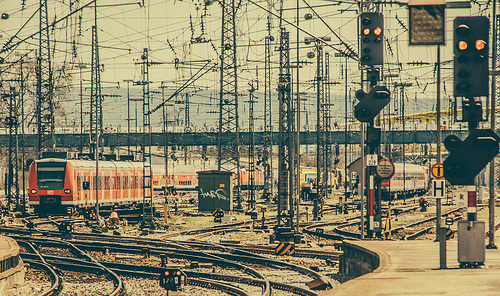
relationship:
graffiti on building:
[199, 186, 229, 202] [197, 171, 230, 213]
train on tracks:
[31, 146, 350, 207] [4, 194, 497, 296]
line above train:
[93, 10, 226, 25] [31, 146, 350, 207]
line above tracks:
[93, 10, 226, 25] [4, 194, 497, 296]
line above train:
[61, 27, 129, 69] [31, 146, 350, 207]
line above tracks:
[61, 27, 129, 69] [4, 194, 497, 296]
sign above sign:
[430, 165, 444, 179] [431, 179, 446, 199]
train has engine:
[31, 146, 350, 207] [31, 159, 180, 214]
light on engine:
[65, 189, 67, 194] [31, 159, 180, 214]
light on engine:
[31, 190, 35, 193] [31, 159, 180, 214]